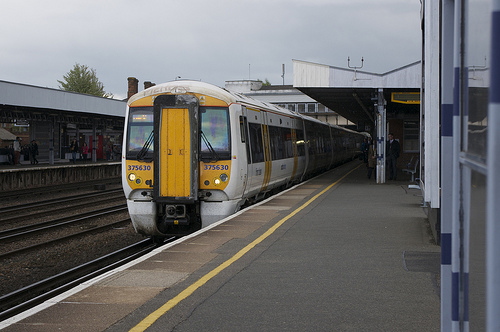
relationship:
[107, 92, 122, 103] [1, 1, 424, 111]
cloud in sky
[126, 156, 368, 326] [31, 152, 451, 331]
line on walkway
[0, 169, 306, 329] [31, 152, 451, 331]
line on walkway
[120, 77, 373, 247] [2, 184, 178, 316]
passenger train on track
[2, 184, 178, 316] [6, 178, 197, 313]
track on ground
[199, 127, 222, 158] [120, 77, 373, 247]
wiper on passenger train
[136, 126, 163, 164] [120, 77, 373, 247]
wiper on passenger train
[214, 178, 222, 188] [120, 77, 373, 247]
light on passenger train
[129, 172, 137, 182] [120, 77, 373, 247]
light on passenger train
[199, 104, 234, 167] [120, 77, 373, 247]
window on passenger train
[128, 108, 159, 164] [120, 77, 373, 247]
window on passenger train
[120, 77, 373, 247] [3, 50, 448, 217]
passenger train at railway station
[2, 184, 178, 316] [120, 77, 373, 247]
track in front of passenger train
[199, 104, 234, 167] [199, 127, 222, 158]
window has wiper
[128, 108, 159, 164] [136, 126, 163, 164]
window has wiper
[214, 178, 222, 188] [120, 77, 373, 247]
light in front of passenger train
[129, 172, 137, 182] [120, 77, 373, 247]
light in front of passenger train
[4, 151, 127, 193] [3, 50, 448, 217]
platform at railway station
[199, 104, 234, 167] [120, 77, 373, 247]
window of passenger train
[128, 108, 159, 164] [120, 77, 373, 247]
window of passenger train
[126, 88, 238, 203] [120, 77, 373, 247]
front of passenger train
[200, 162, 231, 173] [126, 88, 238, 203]
numbers on front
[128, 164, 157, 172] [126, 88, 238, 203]
numbers on front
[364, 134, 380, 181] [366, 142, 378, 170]
woman wearing a coat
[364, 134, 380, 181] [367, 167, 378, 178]
woman wearing pants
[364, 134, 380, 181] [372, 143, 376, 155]
woman wearing a shirt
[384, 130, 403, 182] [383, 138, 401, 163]
man wearing a jacket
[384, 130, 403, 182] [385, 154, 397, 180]
man wearing pants